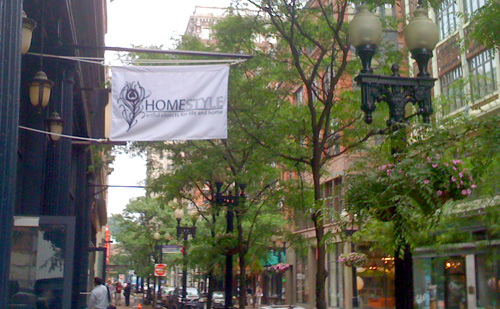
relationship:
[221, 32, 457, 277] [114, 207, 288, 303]
trees in walkway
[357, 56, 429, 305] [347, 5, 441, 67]
lamppost has bulbs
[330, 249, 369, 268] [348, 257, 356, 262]
basket has flowers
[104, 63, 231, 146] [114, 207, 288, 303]
banner over walkway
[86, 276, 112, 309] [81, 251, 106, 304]
person entering door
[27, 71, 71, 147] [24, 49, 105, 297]
fixtures in front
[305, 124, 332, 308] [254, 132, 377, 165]
trunk has branches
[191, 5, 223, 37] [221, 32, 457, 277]
building over trees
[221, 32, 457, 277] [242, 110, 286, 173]
trees have leaves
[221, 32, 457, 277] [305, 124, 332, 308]
trees has trunk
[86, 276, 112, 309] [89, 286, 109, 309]
person has shirt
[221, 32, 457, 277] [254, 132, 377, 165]
trees have branches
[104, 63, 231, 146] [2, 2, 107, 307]
banner on building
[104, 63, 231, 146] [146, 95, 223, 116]
banner has writing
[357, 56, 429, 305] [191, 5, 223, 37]
lamppost on building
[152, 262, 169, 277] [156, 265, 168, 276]
sign has writing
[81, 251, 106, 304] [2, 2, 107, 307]
door on building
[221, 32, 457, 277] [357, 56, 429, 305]
trees near lamppost